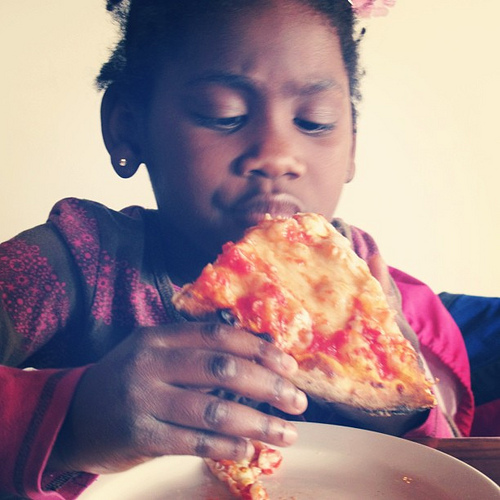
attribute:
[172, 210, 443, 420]
pizza — cheesy, large, toppingless, held, slice, burnt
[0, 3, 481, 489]
child — small, young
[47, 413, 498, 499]
plate — round, white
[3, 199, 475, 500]
sweater — red, dark, pink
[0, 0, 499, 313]
wall — yellow, white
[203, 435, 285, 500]
chunk — small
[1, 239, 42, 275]
flower — star, pink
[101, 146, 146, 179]
earring — diamond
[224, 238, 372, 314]
cheese — bubbly